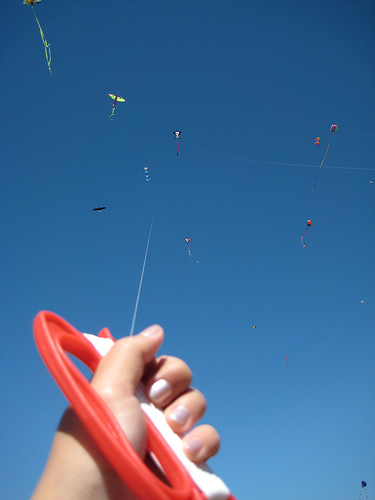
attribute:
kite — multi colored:
[331, 123, 339, 133]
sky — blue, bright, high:
[1, 1, 373, 414]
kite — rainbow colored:
[299, 219, 312, 251]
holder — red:
[32, 306, 253, 497]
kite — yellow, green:
[108, 92, 125, 120]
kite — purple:
[359, 479, 367, 498]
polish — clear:
[185, 436, 202, 451]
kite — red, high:
[299, 219, 310, 248]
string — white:
[121, 303, 145, 319]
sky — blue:
[1, 1, 373, 498]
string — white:
[131, 145, 173, 335]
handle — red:
[34, 309, 239, 499]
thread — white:
[180, 137, 362, 170]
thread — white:
[189, 244, 341, 446]